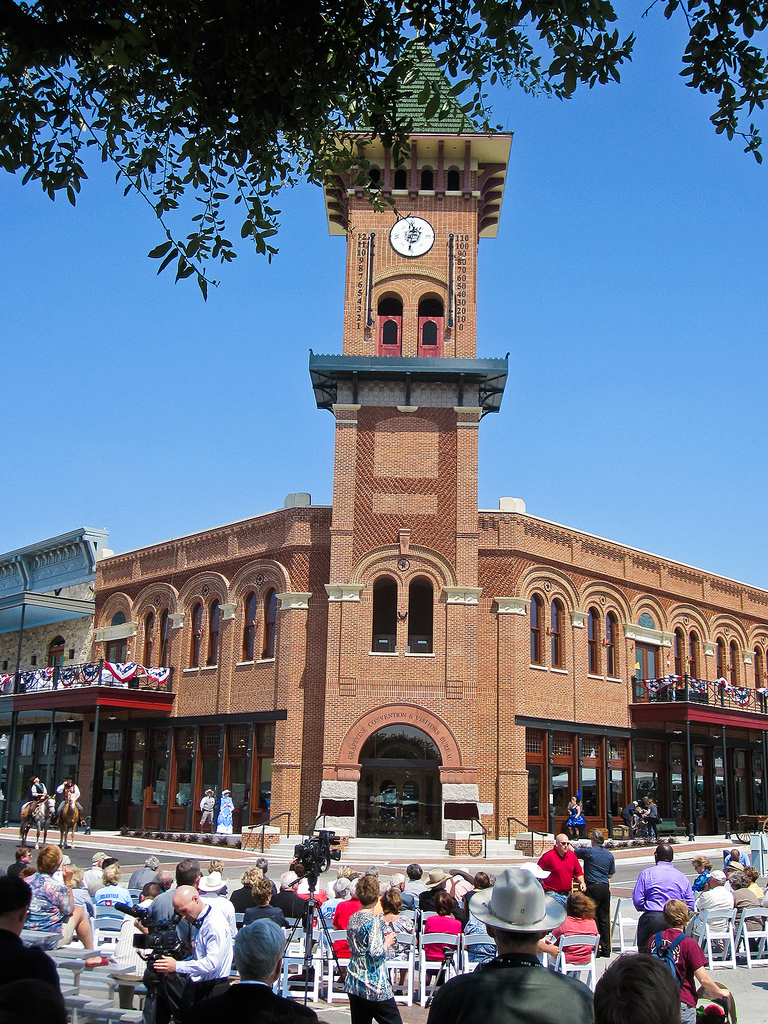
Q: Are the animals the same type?
A: No, they are horses and dogs.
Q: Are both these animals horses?
A: No, they are horses and dogs.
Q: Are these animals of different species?
A: Yes, they are horses and dogs.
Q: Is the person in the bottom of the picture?
A: Yes, the person is in the bottom of the image.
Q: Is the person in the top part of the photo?
A: No, the person is in the bottom of the image.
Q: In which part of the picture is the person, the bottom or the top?
A: The person is in the bottom of the image.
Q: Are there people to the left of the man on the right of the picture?
A: Yes, there is a person to the left of the man.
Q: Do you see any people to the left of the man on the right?
A: Yes, there is a person to the left of the man.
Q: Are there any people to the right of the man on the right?
A: No, the person is to the left of the man.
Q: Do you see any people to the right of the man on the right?
A: No, the person is to the left of the man.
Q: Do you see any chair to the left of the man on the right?
A: No, there is a person to the left of the man.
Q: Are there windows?
A: Yes, there is a window.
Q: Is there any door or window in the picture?
A: Yes, there is a window.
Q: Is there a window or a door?
A: Yes, there is a window.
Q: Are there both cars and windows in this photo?
A: No, there is a window but no cars.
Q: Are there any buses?
A: No, there are no buses.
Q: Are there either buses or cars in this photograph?
A: No, there are no buses or cars.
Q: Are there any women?
A: Yes, there is a woman.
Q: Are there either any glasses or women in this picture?
A: Yes, there is a woman.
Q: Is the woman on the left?
A: Yes, the woman is on the left of the image.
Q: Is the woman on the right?
A: No, the woman is on the left of the image.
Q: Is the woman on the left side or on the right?
A: The woman is on the left of the image.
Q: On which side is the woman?
A: The woman is on the left of the image.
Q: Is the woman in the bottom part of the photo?
A: Yes, the woman is in the bottom of the image.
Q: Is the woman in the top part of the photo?
A: No, the woman is in the bottom of the image.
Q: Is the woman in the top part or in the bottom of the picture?
A: The woman is in the bottom of the image.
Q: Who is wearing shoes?
A: The woman is wearing shoes.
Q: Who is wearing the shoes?
A: The woman is wearing shoes.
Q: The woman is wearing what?
A: The woman is wearing shoes.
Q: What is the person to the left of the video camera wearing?
A: The woman is wearing shoes.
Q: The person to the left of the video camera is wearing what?
A: The woman is wearing shoes.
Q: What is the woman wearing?
A: The woman is wearing shoes.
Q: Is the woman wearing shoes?
A: Yes, the woman is wearing shoes.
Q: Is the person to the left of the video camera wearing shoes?
A: Yes, the woman is wearing shoes.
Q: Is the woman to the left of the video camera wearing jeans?
A: No, the woman is wearing shoes.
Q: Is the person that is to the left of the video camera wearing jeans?
A: No, the woman is wearing shoes.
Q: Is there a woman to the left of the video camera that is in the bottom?
A: Yes, there is a woman to the left of the video camera.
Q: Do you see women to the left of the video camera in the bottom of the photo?
A: Yes, there is a woman to the left of the video camera.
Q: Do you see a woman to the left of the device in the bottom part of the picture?
A: Yes, there is a woman to the left of the video camera.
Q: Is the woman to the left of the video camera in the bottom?
A: Yes, the woman is to the left of the video camera.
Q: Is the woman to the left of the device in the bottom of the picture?
A: Yes, the woman is to the left of the video camera.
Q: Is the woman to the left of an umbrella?
A: No, the woman is to the left of the video camera.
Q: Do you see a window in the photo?
A: Yes, there is a window.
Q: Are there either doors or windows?
A: Yes, there is a window.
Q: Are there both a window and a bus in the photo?
A: No, there is a window but no buses.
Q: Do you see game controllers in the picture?
A: No, there are no game controllers.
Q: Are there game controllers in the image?
A: No, there are no game controllers.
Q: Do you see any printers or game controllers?
A: No, there are no game controllers or printers.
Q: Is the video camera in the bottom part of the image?
A: Yes, the video camera is in the bottom of the image.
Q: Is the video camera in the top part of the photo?
A: No, the video camera is in the bottom of the image.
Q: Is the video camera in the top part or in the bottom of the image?
A: The video camera is in the bottom of the image.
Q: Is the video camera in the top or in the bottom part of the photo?
A: The video camera is in the bottom of the image.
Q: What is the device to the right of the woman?
A: The device is a video camera.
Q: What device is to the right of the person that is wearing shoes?
A: The device is a video camera.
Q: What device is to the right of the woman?
A: The device is a video camera.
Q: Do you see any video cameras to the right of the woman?
A: Yes, there is a video camera to the right of the woman.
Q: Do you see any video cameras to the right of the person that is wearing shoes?
A: Yes, there is a video camera to the right of the woman.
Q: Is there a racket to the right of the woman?
A: No, there is a video camera to the right of the woman.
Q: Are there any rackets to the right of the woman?
A: No, there is a video camera to the right of the woman.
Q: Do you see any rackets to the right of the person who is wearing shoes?
A: No, there is a video camera to the right of the woman.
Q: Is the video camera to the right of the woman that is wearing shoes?
A: Yes, the video camera is to the right of the woman.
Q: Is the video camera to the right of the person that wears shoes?
A: Yes, the video camera is to the right of the woman.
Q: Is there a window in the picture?
A: Yes, there is a window.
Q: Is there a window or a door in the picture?
A: Yes, there is a window.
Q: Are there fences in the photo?
A: No, there are no fences.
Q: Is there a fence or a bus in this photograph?
A: No, there are no fences or buses.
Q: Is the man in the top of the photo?
A: No, the man is in the bottom of the image.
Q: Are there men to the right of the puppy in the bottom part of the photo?
A: Yes, there is a man to the right of the puppy.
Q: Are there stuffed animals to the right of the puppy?
A: No, there is a man to the right of the puppy.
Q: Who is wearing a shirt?
A: The man is wearing a shirt.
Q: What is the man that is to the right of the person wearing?
A: The man is wearing a shirt.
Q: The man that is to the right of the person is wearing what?
A: The man is wearing a shirt.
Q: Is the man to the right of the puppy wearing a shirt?
A: Yes, the man is wearing a shirt.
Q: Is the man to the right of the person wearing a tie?
A: No, the man is wearing a shirt.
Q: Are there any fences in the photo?
A: No, there are no fences.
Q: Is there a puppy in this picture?
A: Yes, there is a puppy.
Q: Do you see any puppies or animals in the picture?
A: Yes, there is a puppy.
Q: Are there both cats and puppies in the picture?
A: No, there is a puppy but no cats.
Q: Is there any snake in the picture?
A: No, there are no snakes.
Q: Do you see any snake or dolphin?
A: No, there are no snakes or dolphins.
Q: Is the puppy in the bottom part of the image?
A: Yes, the puppy is in the bottom of the image.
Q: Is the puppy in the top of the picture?
A: No, the puppy is in the bottom of the image.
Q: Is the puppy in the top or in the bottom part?
A: The puppy is in the bottom of the image.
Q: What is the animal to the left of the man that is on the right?
A: The animal is a puppy.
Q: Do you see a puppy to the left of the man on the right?
A: Yes, there is a puppy to the left of the man.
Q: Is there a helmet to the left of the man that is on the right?
A: No, there is a puppy to the left of the man.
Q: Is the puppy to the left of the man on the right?
A: Yes, the puppy is to the left of the man.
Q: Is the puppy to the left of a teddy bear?
A: No, the puppy is to the left of the man.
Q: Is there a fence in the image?
A: No, there are no fences.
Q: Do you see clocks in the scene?
A: Yes, there is a clock.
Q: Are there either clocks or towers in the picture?
A: Yes, there is a clock.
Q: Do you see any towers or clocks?
A: Yes, there is a clock.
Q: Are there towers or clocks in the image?
A: Yes, there is a clock.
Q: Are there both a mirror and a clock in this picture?
A: No, there is a clock but no mirrors.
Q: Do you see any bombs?
A: No, there are no bombs.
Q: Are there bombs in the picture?
A: No, there are no bombs.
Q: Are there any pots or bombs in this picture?
A: No, there are no bombs or pots.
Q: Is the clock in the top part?
A: Yes, the clock is in the top of the image.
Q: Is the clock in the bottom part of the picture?
A: No, the clock is in the top of the image.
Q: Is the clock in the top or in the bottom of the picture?
A: The clock is in the top of the image.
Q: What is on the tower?
A: The clock is on the tower.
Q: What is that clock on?
A: The clock is on the tower.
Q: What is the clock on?
A: The clock is on the tower.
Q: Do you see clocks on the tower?
A: Yes, there is a clock on the tower.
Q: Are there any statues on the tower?
A: No, there is a clock on the tower.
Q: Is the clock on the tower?
A: Yes, the clock is on the tower.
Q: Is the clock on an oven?
A: No, the clock is on the tower.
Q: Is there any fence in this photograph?
A: No, there are no fences.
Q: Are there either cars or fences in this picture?
A: No, there are no fences or cars.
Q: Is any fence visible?
A: No, there are no fences.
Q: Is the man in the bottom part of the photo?
A: Yes, the man is in the bottom of the image.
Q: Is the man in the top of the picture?
A: No, the man is in the bottom of the image.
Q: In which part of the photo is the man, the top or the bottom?
A: The man is in the bottom of the image.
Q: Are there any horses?
A: Yes, there is a horse.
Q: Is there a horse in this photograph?
A: Yes, there is a horse.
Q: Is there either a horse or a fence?
A: Yes, there is a horse.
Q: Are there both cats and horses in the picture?
A: No, there is a horse but no cats.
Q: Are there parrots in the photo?
A: No, there are no parrots.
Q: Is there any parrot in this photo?
A: No, there are no parrots.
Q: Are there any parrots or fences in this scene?
A: No, there are no parrots or fences.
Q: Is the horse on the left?
A: Yes, the horse is on the left of the image.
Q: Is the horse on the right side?
A: No, the horse is on the left of the image.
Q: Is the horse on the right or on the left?
A: The horse is on the left of the image.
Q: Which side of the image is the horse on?
A: The horse is on the left of the image.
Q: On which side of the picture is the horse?
A: The horse is on the left of the image.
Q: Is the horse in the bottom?
A: Yes, the horse is in the bottom of the image.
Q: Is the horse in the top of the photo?
A: No, the horse is in the bottom of the image.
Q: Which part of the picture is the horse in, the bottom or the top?
A: The horse is in the bottom of the image.